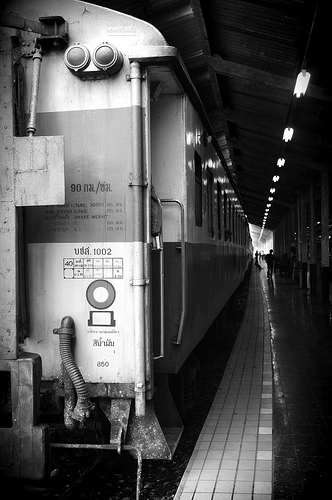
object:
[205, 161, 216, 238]
window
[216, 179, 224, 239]
window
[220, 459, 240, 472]
tile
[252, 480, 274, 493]
tile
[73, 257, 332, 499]
floor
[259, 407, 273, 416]
tile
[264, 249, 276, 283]
person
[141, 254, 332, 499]
platform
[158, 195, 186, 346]
bar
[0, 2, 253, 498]
train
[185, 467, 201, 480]
tiles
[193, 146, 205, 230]
window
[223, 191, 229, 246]
window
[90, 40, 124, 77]
light